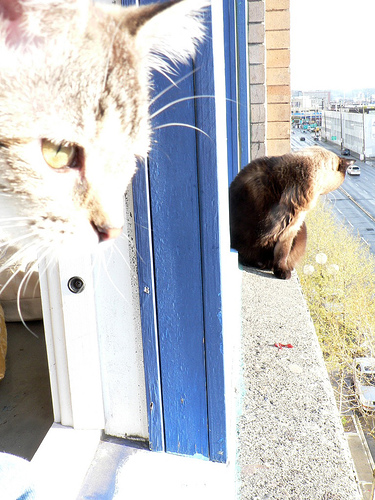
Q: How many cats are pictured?
A: Two.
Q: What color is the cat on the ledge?
A: Brown.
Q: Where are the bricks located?
A: On the building.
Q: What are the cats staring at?
A: The road below.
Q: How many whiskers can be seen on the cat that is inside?
A: Five.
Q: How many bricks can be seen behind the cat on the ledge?
A: Seventeen.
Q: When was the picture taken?
A: During the day.